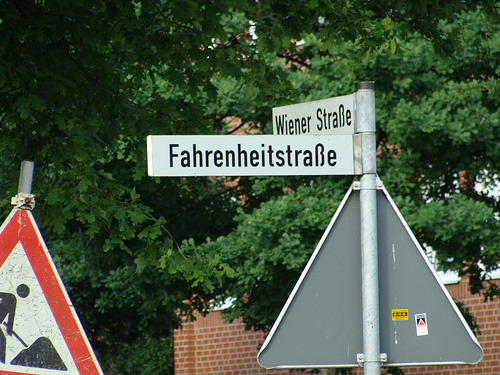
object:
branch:
[447, 158, 490, 201]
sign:
[144, 134, 360, 176]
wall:
[171, 7, 498, 374]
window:
[420, 171, 462, 284]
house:
[171, 39, 499, 374]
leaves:
[1, 2, 493, 252]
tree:
[1, 0, 498, 375]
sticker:
[392, 309, 409, 321]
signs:
[256, 178, 481, 368]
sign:
[271, 87, 378, 136]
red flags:
[0, 203, 106, 375]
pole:
[354, 86, 381, 374]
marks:
[168, 143, 337, 166]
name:
[273, 103, 352, 135]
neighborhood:
[2, 4, 498, 373]